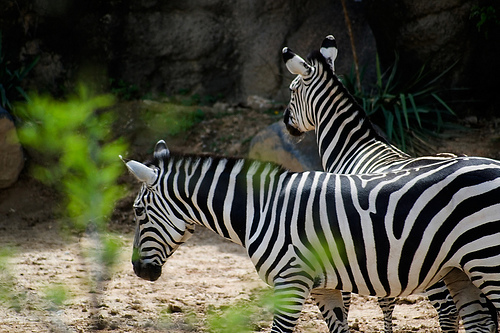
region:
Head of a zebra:
[113, 125, 195, 291]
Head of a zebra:
[264, 21, 351, 143]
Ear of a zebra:
[115, 146, 165, 193]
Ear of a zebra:
[149, 120, 179, 160]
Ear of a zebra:
[271, 37, 316, 81]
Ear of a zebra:
[309, 24, 346, 66]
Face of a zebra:
[119, 183, 151, 293]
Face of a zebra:
[284, 70, 298, 150]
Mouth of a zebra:
[119, 240, 164, 285]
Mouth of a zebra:
[279, 103, 301, 141]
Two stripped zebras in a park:
[117, 44, 498, 331]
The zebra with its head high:
[272, 31, 498, 174]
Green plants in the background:
[0, 0, 495, 331]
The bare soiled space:
[1, 97, 498, 331]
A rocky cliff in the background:
[0, 1, 497, 182]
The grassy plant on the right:
[337, 54, 462, 144]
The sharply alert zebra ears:
[277, 33, 340, 83]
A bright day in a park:
[1, 0, 498, 332]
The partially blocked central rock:
[250, 121, 322, 176]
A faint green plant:
[18, 87, 135, 282]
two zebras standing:
[88, 41, 498, 331]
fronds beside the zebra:
[363, 68, 429, 130]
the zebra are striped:
[91, 73, 497, 287]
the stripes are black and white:
[299, 180, 451, 256]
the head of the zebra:
[98, 136, 220, 291]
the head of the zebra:
[241, 30, 379, 144]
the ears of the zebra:
[116, 141, 188, 187]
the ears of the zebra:
[280, 23, 340, 84]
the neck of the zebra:
[161, 158, 262, 243]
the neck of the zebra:
[311, 93, 359, 144]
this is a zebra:
[140, 137, 467, 250]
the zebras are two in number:
[106, 58, 495, 263]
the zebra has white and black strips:
[335, 204, 410, 307]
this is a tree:
[48, 97, 105, 269]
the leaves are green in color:
[43, 110, 80, 151]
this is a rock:
[203, 29, 265, 94]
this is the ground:
[174, 249, 224, 306]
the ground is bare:
[188, 245, 226, 289]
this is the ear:
[118, 152, 155, 185]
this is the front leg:
[320, 294, 356, 330]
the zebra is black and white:
[115, 135, 493, 329]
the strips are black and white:
[288, 64, 368, 149]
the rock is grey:
[147, 15, 261, 102]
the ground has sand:
[38, 253, 217, 308]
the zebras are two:
[128, 49, 485, 331]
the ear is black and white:
[121, 153, 177, 203]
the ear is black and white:
[278, 49, 321, 87]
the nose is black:
[130, 260, 172, 287]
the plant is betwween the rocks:
[361, 65, 404, 140]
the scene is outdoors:
[4, 5, 497, 331]